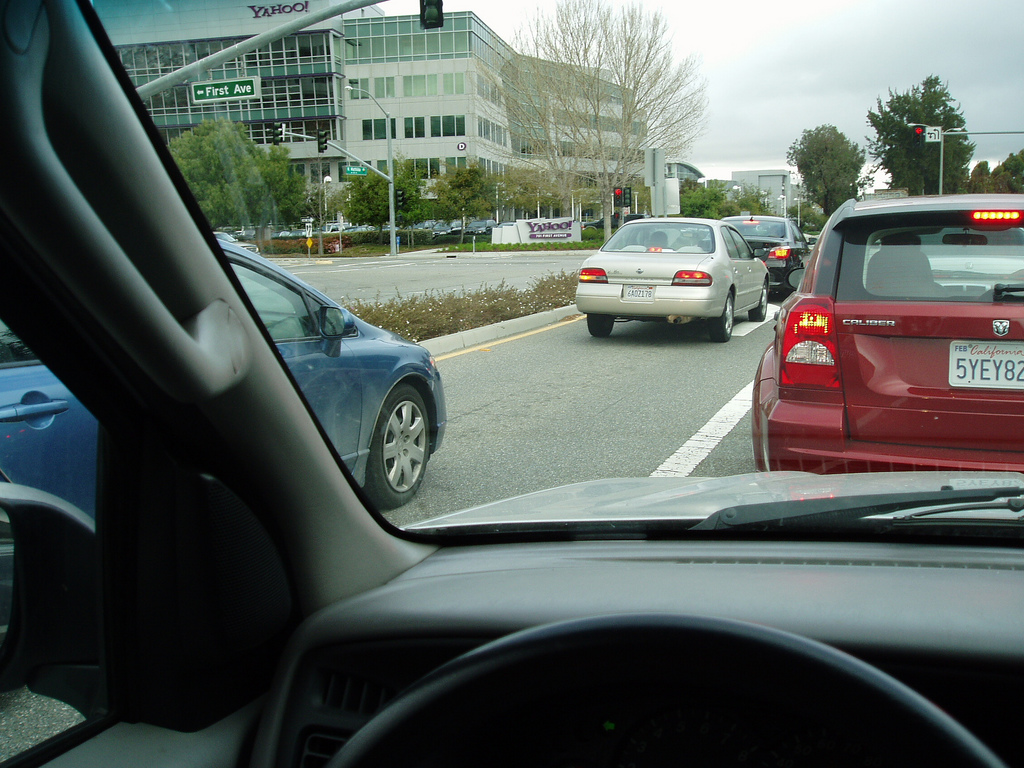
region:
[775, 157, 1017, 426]
red car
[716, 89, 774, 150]
white clouds in blue sky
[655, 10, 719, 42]
white clouds in blue sky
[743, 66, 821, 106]
white clouds in blue sky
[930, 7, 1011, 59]
white clouds in blue sky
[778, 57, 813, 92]
white clouds in blue sky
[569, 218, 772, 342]
a stopped car in street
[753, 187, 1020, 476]
a stopped red car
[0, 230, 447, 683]
a stopped blue car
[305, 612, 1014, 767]
a black steering wheel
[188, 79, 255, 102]
a green street name sign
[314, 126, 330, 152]
an electric traffic signal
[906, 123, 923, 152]
an electric traffic signal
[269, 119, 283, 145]
an electric traffic signal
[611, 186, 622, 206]
an electric traffic signal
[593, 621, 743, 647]
The steering wheel of the car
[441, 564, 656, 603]
The dashboard seen from the interior of car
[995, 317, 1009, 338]
The logo of the car manufacturer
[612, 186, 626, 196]
A red traffic light at the far end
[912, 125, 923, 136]
A red traffic light suspended high on a pole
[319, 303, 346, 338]
The right rear side mirror of vehicle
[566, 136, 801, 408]
the brake lights are on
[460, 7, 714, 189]
the tree is bare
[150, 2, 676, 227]
a building to the left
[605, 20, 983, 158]
the sky is overcast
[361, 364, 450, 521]
the wheel is black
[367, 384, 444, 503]
the rim is silver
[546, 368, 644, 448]
the street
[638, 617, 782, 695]
a steering wheel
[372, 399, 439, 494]
front tire of the car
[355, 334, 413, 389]
the car is blue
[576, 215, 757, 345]
a tanned car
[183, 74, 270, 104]
a street sign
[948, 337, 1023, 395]
a license plate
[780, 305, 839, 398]
a light on the car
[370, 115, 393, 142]
A window on a building.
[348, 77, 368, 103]
A window on a building.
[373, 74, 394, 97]
A window on a building.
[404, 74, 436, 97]
A window on a building.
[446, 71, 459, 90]
A window on a building.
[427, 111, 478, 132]
A window on a building.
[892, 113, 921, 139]
green leaves on the tree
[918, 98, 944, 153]
green leaves on the tree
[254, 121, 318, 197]
green leaves on the tree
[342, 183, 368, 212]
green leaves on the tree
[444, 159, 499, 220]
green leaves on the tree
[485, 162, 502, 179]
green leaves on the tree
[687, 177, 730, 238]
green leaves on the tree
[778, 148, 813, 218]
green leaves on the tree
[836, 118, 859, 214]
green leaves on the tree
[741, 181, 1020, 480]
red car driving in street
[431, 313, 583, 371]
yellow line drawn on street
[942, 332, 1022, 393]
license plate on back of red car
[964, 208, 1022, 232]
red row of mini lights at top of back windshield on red car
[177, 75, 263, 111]
green street sign above street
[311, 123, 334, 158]
black traffic light hanging from pole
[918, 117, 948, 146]
black and white traffic sign on pole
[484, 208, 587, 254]
white yahoo sign in front of building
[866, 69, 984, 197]
tall green tree behind red street light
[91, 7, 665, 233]
a large white building